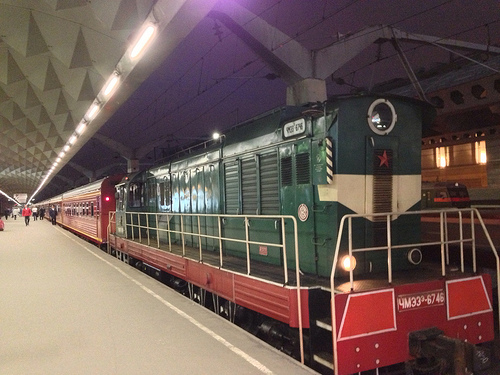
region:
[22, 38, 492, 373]
A train sitting at station.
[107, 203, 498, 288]
Silver railing on train.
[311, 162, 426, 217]
A section of train car is white.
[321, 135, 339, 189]
A small black and white pole.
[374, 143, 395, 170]
Red star on train.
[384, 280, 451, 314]
A tag with white numbers and letters.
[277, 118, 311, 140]
A white square sign.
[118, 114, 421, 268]
A green train car.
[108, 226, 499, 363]
Bottom of train car is red.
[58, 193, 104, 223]
Passenger windows on train car.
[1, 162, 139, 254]
the train is in the station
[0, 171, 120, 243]
the train is red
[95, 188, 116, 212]
the light is on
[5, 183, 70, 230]
people are in the station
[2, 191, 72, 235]
people are walking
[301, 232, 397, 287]
the headlight is on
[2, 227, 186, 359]
the ground is grey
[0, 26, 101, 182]
the ceiling has triangle shapes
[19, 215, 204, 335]
a white line on the platform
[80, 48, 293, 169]
wires above the train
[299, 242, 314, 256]
side of a train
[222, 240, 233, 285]
part of a train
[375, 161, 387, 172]
part of a train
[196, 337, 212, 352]
part of a path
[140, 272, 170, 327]
edge of a rail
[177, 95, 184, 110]
part of the sky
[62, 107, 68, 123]
part of the light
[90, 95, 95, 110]
part of the roof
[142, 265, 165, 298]
edge of a path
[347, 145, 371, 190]
part of a train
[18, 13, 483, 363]
train in a modern station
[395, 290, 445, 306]
identification number for the vehicle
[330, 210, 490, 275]
railing of the first car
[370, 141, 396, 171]
five pointed red star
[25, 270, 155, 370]
long, clean platform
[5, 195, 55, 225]
commuters walk along the platform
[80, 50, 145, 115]
lights running along the overhang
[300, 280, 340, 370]
steps up to the engine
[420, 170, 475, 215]
train on another track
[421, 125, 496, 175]
lights inside the building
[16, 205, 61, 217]
Person wearing red shirt.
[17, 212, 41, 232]
Person wearing black pants.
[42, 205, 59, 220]
Person wearing dark coat.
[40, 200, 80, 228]
Person standing next to train.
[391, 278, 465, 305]
White writing on train car.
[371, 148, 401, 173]
Red star on train car.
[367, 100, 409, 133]
Round window on train car.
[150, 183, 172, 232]
Green door on side of train car.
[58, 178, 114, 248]
Red train car behind green car.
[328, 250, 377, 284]
White light illuminated on train car.